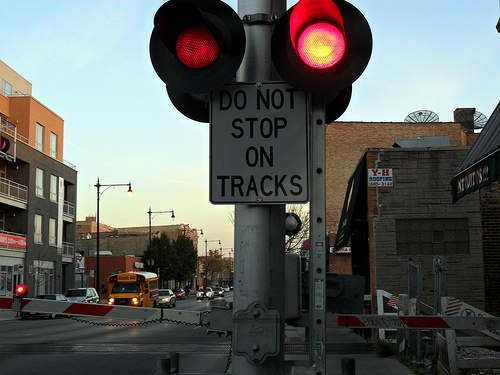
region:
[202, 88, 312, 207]
Sign warning not to stop on the tracks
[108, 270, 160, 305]
School bus approaching rail crossing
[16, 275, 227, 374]
Safety bar at the rail crossing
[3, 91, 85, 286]
Old buildings on the street corner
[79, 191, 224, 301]
Traffic approaching a rail crossing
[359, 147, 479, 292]
Old building on a street corner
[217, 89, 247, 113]
The word Do in front of NOT.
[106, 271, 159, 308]
A small yellow school bus.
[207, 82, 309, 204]
White and black sign under the train lights.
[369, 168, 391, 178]
Red Y-H on a building.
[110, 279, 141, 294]
Windshield on a bus.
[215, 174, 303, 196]
Black word TRACKS.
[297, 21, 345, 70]
Most illuminated red light above the TRACKS sign.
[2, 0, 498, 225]
A blue and white sky.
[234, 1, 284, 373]
A tall grey pole holding a sign and train lights.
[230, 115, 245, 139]
Black S in STOP.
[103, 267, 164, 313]
School bus at the stop sign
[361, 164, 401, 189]
white sign on a building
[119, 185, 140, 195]
Light above the street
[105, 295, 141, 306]
lights on the school bus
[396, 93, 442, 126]
satellite dish on top of building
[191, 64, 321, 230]
traffic sign on a pole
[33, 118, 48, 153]
large window on the building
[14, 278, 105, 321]
cars parked on the street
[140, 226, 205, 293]
trees on the curb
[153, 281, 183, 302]
car behind the bus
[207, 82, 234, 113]
black letter on sign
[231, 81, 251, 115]
black letter on sign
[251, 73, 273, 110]
black letter on sign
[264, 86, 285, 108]
black letter on sign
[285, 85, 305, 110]
black letter on sign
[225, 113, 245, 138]
black letter on sign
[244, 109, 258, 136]
black letter on sign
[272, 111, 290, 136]
black letter on sign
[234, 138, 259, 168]
black letter on sign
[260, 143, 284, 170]
black letter on sign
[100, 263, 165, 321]
School bus waiting for a train to pass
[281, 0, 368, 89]
Light is bright and lit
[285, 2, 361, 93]
Light is on and red colored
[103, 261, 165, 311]
Yellow school bus in line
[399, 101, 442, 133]
Satellite on top of a building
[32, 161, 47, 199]
Window on a building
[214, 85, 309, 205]
"DO NOT STOP ON TRACKS" is written on the sign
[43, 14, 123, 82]
Large body of blue skies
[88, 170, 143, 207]
Street light is on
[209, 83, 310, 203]
the sign board has letters in black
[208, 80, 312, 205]
the sign board is screwed at top and bottom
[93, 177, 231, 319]
tall street lamps are along the roadside